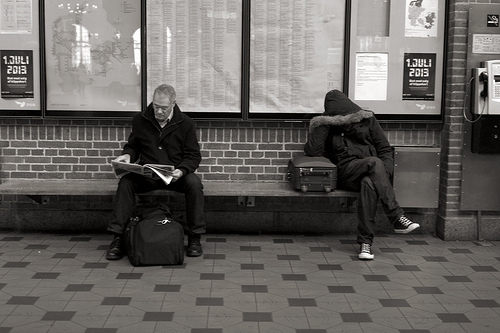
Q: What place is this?
A: It is a terminal.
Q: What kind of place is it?
A: It is a terminal.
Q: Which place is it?
A: It is a terminal.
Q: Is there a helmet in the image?
A: No, there are no helmets.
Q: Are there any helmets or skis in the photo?
A: No, there are no helmets or skis.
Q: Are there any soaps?
A: No, there are no soaps.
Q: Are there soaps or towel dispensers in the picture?
A: No, there are no soaps or towel dispensers.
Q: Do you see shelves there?
A: No, there are no shelves.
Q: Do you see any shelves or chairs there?
A: No, there are no shelves or chairs.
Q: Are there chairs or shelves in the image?
A: No, there are no shelves or chairs.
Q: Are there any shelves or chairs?
A: No, there are no shelves or chairs.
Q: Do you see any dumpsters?
A: No, there are no dumpsters.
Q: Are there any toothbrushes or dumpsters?
A: No, there are no dumpsters or toothbrushes.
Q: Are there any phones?
A: Yes, there is a phone.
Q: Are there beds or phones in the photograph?
A: Yes, there is a phone.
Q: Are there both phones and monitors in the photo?
A: No, there is a phone but no monitors.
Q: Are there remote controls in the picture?
A: No, there are no remote controls.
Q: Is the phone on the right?
A: Yes, the phone is on the right of the image.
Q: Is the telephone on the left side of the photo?
A: No, the telephone is on the right of the image.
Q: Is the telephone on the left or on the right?
A: The telephone is on the right of the image.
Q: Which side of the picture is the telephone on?
A: The telephone is on the right of the image.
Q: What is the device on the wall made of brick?
A: The device is a phone.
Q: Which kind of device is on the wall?
A: The device is a phone.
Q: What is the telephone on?
A: The telephone is on the wall.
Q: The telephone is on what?
A: The telephone is on the wall.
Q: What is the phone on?
A: The telephone is on the wall.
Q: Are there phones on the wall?
A: Yes, there is a phone on the wall.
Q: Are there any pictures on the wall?
A: No, there is a phone on the wall.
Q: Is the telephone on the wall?
A: Yes, the telephone is on the wall.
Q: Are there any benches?
A: Yes, there is a bench.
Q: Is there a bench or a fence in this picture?
A: Yes, there is a bench.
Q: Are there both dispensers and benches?
A: No, there is a bench but no dispensers.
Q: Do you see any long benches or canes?
A: Yes, there is a long bench.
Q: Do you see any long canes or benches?
A: Yes, there is a long bench.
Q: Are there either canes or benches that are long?
A: Yes, the bench is long.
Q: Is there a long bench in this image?
A: Yes, there is a long bench.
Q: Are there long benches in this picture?
A: Yes, there is a long bench.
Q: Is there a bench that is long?
A: Yes, there is a bench that is long.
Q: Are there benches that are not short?
A: Yes, there is a long bench.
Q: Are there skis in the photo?
A: No, there are no skis.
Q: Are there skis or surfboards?
A: No, there are no skis or surfboards.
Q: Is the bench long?
A: Yes, the bench is long.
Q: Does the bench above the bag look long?
A: Yes, the bench is long.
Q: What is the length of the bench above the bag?
A: The bench is long.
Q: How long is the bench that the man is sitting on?
A: The bench is long.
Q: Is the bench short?
A: No, the bench is long.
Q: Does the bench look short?
A: No, the bench is long.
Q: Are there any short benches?
A: No, there is a bench but it is long.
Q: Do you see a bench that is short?
A: No, there is a bench but it is long.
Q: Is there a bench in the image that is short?
A: No, there is a bench but it is long.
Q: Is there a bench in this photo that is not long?
A: No, there is a bench but it is long.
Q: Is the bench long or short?
A: The bench is long.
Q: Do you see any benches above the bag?
A: Yes, there is a bench above the bag.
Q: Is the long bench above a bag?
A: Yes, the bench is above a bag.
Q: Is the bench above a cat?
A: No, the bench is above a bag.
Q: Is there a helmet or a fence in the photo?
A: No, there are no helmets or fences.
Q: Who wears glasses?
A: The man wears glasses.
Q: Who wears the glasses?
A: The man wears glasses.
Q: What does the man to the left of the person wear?
A: The man wears glasses.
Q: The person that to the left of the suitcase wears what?
A: The man wears glasses.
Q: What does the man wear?
A: The man wears glasses.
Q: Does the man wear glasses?
A: Yes, the man wears glasses.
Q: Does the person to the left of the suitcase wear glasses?
A: Yes, the man wears glasses.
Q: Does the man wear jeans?
A: No, the man wears glasses.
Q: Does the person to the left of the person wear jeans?
A: No, the man wears glasses.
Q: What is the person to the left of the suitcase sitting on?
A: The man is sitting on the bench.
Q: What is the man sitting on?
A: The man is sitting on the bench.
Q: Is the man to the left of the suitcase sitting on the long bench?
A: Yes, the man is sitting on the bench.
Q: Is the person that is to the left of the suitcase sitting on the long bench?
A: Yes, the man is sitting on the bench.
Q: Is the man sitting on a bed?
A: No, the man is sitting on the bench.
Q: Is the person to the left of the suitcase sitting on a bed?
A: No, the man is sitting on the bench.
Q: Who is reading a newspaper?
A: The man is reading a newspaper.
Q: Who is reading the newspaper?
A: The man is reading a newspaper.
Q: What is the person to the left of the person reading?
A: The man is reading a newspaper.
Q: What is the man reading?
A: The man is reading a newspaper.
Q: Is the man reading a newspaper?
A: Yes, the man is reading a newspaper.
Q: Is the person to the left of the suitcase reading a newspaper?
A: Yes, the man is reading a newspaper.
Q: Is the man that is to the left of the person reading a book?
A: No, the man is reading a newspaper.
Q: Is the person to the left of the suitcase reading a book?
A: No, the man is reading a newspaper.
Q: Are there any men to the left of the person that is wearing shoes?
A: Yes, there is a man to the left of the person.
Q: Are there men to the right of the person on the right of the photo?
A: No, the man is to the left of the person.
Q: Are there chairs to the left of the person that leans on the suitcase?
A: No, there is a man to the left of the person.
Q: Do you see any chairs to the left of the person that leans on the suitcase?
A: No, there is a man to the left of the person.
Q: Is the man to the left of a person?
A: Yes, the man is to the left of a person.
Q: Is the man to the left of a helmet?
A: No, the man is to the left of a person.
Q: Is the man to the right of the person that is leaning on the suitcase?
A: No, the man is to the left of the person.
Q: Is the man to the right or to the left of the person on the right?
A: The man is to the left of the person.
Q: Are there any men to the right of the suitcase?
A: No, the man is to the left of the suitcase.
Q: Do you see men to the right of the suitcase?
A: No, the man is to the left of the suitcase.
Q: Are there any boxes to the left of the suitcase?
A: No, there is a man to the left of the suitcase.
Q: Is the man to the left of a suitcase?
A: Yes, the man is to the left of a suitcase.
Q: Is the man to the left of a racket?
A: No, the man is to the left of a suitcase.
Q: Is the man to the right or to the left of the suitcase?
A: The man is to the left of the suitcase.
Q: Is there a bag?
A: Yes, there is a bag.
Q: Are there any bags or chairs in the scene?
A: Yes, there is a bag.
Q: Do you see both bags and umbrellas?
A: No, there is a bag but no umbrellas.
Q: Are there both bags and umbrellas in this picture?
A: No, there is a bag but no umbrellas.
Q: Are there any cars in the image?
A: No, there are no cars.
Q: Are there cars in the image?
A: No, there are no cars.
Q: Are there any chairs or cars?
A: No, there are no cars or chairs.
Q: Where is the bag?
A: The bag is on the floor.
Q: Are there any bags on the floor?
A: Yes, there is a bag on the floor.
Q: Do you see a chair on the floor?
A: No, there is a bag on the floor.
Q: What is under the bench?
A: The bag is under the bench.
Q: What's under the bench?
A: The bag is under the bench.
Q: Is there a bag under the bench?
A: Yes, there is a bag under the bench.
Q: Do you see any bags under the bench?
A: Yes, there is a bag under the bench.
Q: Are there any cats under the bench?
A: No, there is a bag under the bench.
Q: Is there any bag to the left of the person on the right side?
A: Yes, there is a bag to the left of the person.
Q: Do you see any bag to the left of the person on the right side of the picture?
A: Yes, there is a bag to the left of the person.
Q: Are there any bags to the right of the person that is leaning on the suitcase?
A: No, the bag is to the left of the person.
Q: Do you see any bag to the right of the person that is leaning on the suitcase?
A: No, the bag is to the left of the person.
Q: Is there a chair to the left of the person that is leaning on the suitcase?
A: No, there is a bag to the left of the person.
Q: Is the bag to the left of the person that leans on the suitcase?
A: Yes, the bag is to the left of the person.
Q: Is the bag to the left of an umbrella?
A: No, the bag is to the left of the person.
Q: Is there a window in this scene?
A: Yes, there is a window.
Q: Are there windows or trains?
A: Yes, there is a window.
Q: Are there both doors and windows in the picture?
A: No, there is a window but no doors.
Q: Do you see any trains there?
A: No, there are no trains.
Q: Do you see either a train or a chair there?
A: No, there are no trains or chairs.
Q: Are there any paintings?
A: No, there are no paintings.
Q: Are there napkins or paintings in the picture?
A: No, there are no paintings or napkins.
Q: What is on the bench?
A: The suitcase is on the bench.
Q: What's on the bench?
A: The suitcase is on the bench.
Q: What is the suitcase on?
A: The suitcase is on the bench.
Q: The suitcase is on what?
A: The suitcase is on the bench.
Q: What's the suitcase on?
A: The suitcase is on the bench.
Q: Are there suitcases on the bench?
A: Yes, there is a suitcase on the bench.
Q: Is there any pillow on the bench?
A: No, there is a suitcase on the bench.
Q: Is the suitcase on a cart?
A: No, the suitcase is on a bench.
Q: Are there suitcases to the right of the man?
A: Yes, there is a suitcase to the right of the man.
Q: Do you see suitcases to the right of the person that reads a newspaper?
A: Yes, there is a suitcase to the right of the man.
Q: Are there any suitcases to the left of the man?
A: No, the suitcase is to the right of the man.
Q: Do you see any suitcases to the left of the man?
A: No, the suitcase is to the right of the man.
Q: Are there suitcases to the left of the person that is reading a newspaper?
A: No, the suitcase is to the right of the man.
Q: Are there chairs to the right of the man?
A: No, there is a suitcase to the right of the man.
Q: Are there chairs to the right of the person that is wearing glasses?
A: No, there is a suitcase to the right of the man.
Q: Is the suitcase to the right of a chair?
A: No, the suitcase is to the right of the man.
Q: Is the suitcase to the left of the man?
A: No, the suitcase is to the right of the man.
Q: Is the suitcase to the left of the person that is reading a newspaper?
A: No, the suitcase is to the right of the man.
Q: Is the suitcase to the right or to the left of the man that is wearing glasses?
A: The suitcase is to the right of the man.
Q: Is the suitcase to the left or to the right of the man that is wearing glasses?
A: The suitcase is to the right of the man.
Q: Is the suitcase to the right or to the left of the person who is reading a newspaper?
A: The suitcase is to the right of the man.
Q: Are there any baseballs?
A: No, there are no baseballs.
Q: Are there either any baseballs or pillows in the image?
A: No, there are no baseballs or pillows.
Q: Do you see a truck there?
A: No, there are no trucks.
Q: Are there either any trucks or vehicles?
A: No, there are no trucks or vehicles.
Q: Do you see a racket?
A: No, there are no rackets.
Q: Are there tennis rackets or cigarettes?
A: No, there are no tennis rackets or cigarettes.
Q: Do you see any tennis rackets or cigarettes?
A: No, there are no tennis rackets or cigarettes.